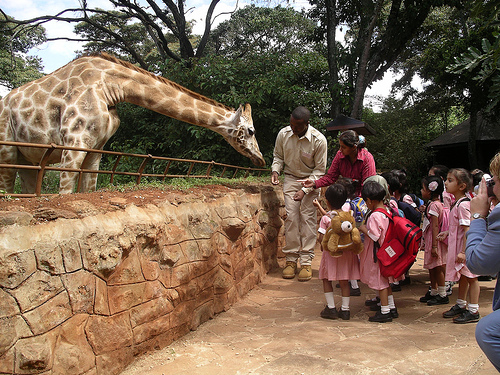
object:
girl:
[419, 176, 450, 306]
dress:
[358, 206, 391, 290]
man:
[465, 148, 500, 375]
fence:
[0, 140, 271, 201]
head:
[338, 130, 367, 156]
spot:
[80, 89, 98, 114]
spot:
[57, 168, 67, 178]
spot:
[26, 127, 50, 141]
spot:
[229, 114, 238, 122]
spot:
[74, 113, 78, 130]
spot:
[215, 107, 225, 117]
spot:
[7, 94, 21, 106]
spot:
[80, 67, 98, 79]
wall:
[2, 187, 279, 375]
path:
[115, 260, 497, 371]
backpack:
[372, 202, 422, 280]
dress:
[317, 209, 360, 282]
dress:
[420, 200, 451, 269]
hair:
[292, 106, 312, 124]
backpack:
[321, 210, 365, 258]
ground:
[191, 307, 476, 375]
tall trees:
[0, 0, 500, 131]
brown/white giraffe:
[0, 50, 266, 198]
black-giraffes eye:
[246, 127, 255, 137]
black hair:
[325, 184, 350, 210]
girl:
[358, 180, 422, 322]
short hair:
[360, 179, 387, 201]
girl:
[317, 183, 361, 320]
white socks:
[324, 292, 335, 308]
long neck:
[105, 56, 218, 141]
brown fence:
[0, 191, 103, 209]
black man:
[271, 106, 327, 280]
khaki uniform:
[270, 124, 330, 265]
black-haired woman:
[296, 130, 377, 200]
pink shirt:
[313, 148, 377, 190]